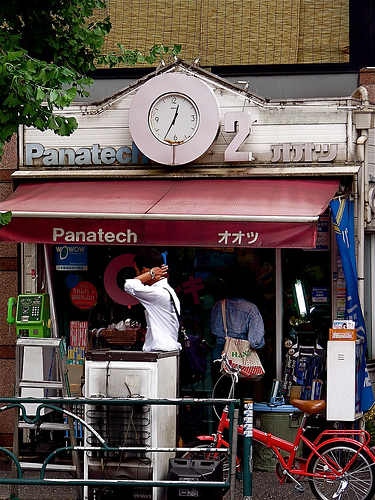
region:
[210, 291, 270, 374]
woman with a bag around her chest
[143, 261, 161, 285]
watch on man's left wrist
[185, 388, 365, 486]
red bicycle leaning against metal railing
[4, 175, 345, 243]
red awning with white lettering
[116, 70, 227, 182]
white clock above storefront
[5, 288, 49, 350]
old fashioned telephone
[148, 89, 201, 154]
four black numbers on the clock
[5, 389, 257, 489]
green metal railing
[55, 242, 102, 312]
signs on store's window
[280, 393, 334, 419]
brown seat of bicycle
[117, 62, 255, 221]
white circle clock on board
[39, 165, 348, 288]
red tent for store front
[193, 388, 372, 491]
red bike parked in front of store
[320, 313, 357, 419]
white mail box for store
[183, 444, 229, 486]
small black computer monitor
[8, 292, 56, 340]
lime and green telephone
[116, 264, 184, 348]
white dress shirt on man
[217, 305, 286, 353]
jean jacket on woman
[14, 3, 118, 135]
large green treet on sidewalk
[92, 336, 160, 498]
white old fridge out on sidewalk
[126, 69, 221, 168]
a white round clock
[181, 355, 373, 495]
a red framed bike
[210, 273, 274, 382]
a person carrying a bag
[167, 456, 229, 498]
back of a tv on the ground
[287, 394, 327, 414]
a shiny brown bike seat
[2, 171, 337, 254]
a maroon canopy over a business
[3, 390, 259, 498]
metal rail painted green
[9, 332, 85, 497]
ladder leaning on a metal railing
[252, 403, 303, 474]
a tin trash can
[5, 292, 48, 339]
a lime green phone system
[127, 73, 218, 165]
a clock on a building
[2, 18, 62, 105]
the leaves of a tree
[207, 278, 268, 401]
a person wearing blue carrying a white bag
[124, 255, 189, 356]
a man wearing a white shirt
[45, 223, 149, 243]
white lettering on an awning of a business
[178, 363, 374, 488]
a red bicycle parked on the sidewalk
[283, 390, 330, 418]
a brown bicycle seat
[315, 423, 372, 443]
a carry rack on the back of a bicycle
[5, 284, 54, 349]
a green public telephone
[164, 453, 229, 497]
a small tv on the sidewalk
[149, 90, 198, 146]
clock on top of building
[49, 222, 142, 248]
the word pantech on red awning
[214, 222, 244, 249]
asian language on red awning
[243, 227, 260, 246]
smiley sign on red awning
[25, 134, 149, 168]
pantech sign on top of building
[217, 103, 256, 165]
The number 2 on top of building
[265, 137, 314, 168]
Asian writing on top of building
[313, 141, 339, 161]
smiley face on top of building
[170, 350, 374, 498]
small red bicycle outside of building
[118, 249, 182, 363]
person with his hand on back of neck outside of buildig